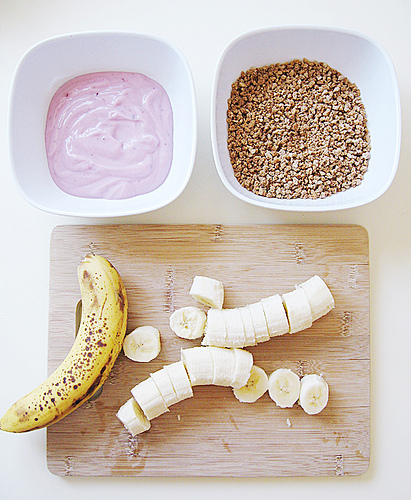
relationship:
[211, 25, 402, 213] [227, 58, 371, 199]
bowl had granola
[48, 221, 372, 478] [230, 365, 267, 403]
board has sliced banana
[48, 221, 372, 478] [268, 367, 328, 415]
board has banana slice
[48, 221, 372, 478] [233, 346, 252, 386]
board has sliced banana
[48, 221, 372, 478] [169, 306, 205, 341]
board has banana slice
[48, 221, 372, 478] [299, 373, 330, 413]
board has sliced banana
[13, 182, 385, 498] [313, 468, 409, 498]
counter has edge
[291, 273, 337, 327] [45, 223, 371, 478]
banana on board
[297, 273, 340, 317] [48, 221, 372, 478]
slice on board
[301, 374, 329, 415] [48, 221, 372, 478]
banana slice on board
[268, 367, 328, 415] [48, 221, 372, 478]
banana slice on board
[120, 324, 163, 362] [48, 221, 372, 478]
banana slice on board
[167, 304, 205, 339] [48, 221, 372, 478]
banana slice on board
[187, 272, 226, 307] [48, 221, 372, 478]
banana slice on board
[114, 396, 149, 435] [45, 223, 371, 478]
slice on board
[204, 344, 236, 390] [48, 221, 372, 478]
slice on board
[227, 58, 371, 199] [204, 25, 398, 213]
granola in bowl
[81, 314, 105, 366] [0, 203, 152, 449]
spot on banana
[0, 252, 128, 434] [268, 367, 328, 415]
banana on banana slice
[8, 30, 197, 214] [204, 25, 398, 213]
bowl white like th one bowl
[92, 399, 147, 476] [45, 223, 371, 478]
banana juice on board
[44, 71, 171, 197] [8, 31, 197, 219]
pink yogurt in a bowl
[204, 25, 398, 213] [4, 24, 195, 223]
bowl sitting beside bowl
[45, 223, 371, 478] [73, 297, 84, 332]
board has a handle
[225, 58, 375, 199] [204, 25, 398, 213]
granola in a bowl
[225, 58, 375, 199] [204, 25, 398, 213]
granola inside bowl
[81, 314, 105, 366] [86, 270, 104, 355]
spot are on banana peel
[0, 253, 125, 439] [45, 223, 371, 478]
banana on top of board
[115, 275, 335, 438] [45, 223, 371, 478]
banana on top of board